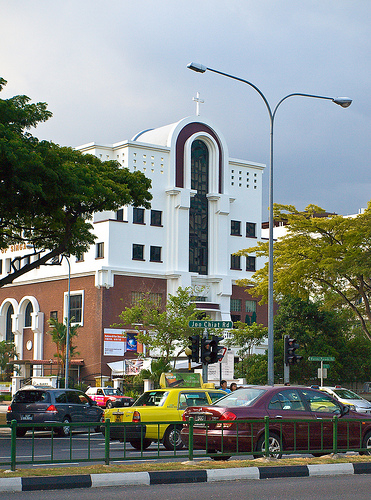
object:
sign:
[188, 320, 233, 328]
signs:
[308, 355, 336, 362]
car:
[178, 379, 371, 462]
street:
[0, 402, 371, 471]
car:
[99, 368, 230, 451]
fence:
[0, 412, 371, 473]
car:
[4, 376, 106, 439]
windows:
[133, 245, 142, 259]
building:
[1, 91, 282, 388]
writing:
[0, 240, 30, 255]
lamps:
[183, 60, 212, 78]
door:
[263, 390, 312, 449]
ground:
[0, 430, 371, 500]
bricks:
[90, 293, 96, 299]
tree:
[231, 201, 371, 343]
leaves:
[323, 232, 331, 243]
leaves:
[79, 163, 83, 168]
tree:
[0, 73, 153, 286]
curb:
[0, 454, 371, 493]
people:
[229, 381, 239, 392]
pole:
[201, 364, 208, 384]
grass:
[0, 452, 371, 481]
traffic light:
[183, 332, 200, 367]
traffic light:
[282, 332, 297, 368]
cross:
[192, 90, 206, 115]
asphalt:
[0, 473, 371, 500]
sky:
[0, 0, 368, 214]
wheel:
[255, 429, 287, 459]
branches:
[0, 196, 109, 288]